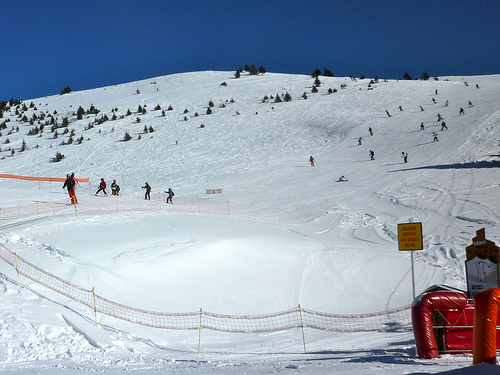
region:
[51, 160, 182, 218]
several skiers are on the hils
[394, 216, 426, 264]
Yellow sign gives a warning to the skiers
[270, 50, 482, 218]
Skiers are on their way down the hill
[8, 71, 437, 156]
Trees pepper the side of the ski hill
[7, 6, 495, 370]
Snow covers the side of the hill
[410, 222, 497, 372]
A station is at the bottom of the hill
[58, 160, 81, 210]
person skiing in white snow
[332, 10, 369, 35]
white clouds in blue sky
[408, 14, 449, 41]
white clouds in blue sky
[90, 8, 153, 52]
white clouds in blue sky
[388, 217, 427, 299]
The yellow sign on the slope.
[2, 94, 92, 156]
The green trees on the slope.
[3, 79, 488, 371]
The slope has snow on it.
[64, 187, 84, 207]
The man has on a orange pant.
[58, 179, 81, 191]
The man is wearing a black jacket.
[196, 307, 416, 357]
There is a net on the slope.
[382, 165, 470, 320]
The are tracks on the slope.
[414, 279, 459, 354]
The red tube on the slope.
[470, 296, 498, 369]
The orange tube on the slope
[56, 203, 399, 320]
The smooth area of the snow.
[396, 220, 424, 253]
yellow sign with red writing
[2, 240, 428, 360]
red fence made of netting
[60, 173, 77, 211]
person with orange pants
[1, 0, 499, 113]
blue sky above a mountain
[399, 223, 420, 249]
writing on a sign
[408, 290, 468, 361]
red hose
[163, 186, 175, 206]
person with a blue jacket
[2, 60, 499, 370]
snow covered mountain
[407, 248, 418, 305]
grey sign post holding a yellow sign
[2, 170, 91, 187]
darker red fence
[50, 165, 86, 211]
a person sking on snow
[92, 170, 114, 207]
a person sking on snow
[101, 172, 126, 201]
a person sking on snow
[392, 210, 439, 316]
a view of pole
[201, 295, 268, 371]
a view of fence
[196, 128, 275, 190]
a view of snow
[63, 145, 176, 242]
a view of group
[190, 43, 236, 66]
a view of sky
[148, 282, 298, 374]
a view of fence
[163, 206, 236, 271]
a view of ice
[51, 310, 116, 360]
a view of marks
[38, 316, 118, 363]
few mark in the ice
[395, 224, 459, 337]
a view of board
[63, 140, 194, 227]
a view of people